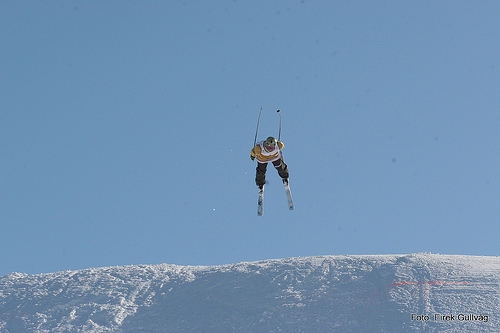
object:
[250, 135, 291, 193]
man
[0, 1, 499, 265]
sky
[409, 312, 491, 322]
logo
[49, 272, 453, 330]
ground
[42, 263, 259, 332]
snow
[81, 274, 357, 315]
tracks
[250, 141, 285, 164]
jacket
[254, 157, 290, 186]
pants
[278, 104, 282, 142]
poles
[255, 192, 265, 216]
skis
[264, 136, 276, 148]
helmet